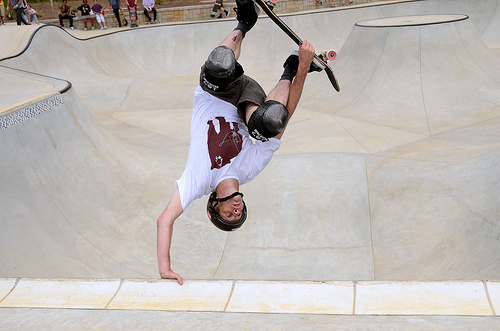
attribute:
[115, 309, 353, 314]
edge — yellow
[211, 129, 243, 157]
bear — brown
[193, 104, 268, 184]
shirt — burgundy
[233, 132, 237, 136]
muzzle — white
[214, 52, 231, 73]
kneepad — grey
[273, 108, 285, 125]
kneepad — grey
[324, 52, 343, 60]
wheel — white, orange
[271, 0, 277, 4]
wheel — white, orange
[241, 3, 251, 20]
sneaker — black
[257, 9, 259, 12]
rubber sole — white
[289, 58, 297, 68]
sneaker — black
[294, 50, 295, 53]
rubber sole — white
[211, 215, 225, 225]
helmet — black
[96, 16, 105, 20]
pants — white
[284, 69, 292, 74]
sock — black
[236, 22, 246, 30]
sock — black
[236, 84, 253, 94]
pants — black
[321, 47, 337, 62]
wheels — skateboard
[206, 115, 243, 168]
bear — brown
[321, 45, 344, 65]
wheels — red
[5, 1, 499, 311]
skate trail — white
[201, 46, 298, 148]
knee pads — black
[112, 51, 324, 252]
skater — upside down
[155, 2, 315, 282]
boy — skating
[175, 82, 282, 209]
shirt — white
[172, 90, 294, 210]
shirt — white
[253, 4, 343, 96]
skateboard — wood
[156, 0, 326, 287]
skater — upside down, supporting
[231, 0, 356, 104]
board — in air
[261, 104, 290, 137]
kneepads — black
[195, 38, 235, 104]
pad — knee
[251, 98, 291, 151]
pad — knee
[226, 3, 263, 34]
shoe — black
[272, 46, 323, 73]
shoe — black